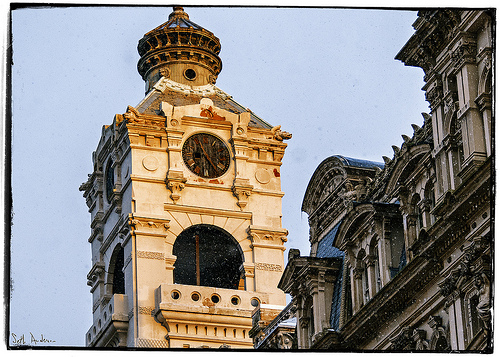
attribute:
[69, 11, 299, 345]
tower — fancy, ornate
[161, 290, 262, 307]
holes — small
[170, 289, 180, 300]
opening — circular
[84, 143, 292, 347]
concrete — light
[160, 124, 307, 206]
clock — rusted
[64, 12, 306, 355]
building — fancy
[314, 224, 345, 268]
tiles — blue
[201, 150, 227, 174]
hand — long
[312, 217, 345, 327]
color — blue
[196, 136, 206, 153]
hand — short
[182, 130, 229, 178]
face — black